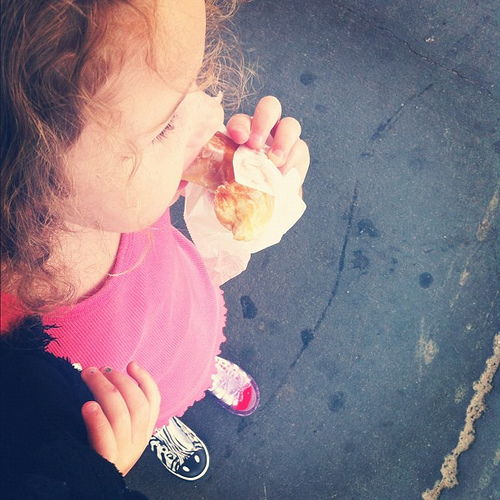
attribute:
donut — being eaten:
[185, 127, 268, 228]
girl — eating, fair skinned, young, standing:
[1, 0, 311, 499]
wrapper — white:
[179, 125, 310, 290]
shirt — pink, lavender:
[2, 207, 229, 430]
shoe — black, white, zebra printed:
[148, 417, 214, 483]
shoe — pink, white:
[210, 353, 261, 419]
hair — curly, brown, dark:
[1, 0, 256, 323]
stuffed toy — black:
[0, 312, 151, 500]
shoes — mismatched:
[148, 351, 263, 481]